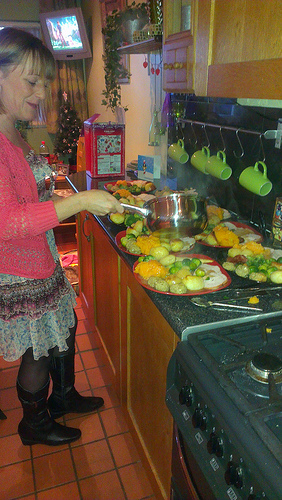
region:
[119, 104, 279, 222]
coffee cups hanging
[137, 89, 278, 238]
green coffee cups hanging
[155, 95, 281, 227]
coffee cups hanging on hooks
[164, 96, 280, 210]
green coffee cups hanging on hooks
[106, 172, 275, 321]
plates of food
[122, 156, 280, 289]
plates of food on the counter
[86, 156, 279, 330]
food on plates on the counter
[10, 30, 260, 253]
a woman holding a pot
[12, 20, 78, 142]
a woman that is smiling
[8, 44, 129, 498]
a woman wearing boots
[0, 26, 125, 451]
Woman preparing a meal in the kitchen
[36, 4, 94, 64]
TV monitor hanging on the wall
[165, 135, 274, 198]
Four green hanging cups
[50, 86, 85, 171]
Small Christmas tree in the corner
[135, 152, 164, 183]
Christmas card on the counter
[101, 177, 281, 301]
Plates full of food on the counter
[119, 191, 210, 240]
Stainless steel pot the woman is holding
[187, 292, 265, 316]
Dirty spoon lying on the counter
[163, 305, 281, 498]
Black range next to the counter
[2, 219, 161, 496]
Brown floor tile in the kitchen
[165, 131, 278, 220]
green mugs hanging on rack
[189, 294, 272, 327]
silver spoon on table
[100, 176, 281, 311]
plates of food on counter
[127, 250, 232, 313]
red plate on counter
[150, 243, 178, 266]
potatoes on plate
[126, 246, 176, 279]
butternut on plate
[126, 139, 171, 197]
christmas card on counter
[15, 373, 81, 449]
lady wearing boots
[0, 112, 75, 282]
lady wearing pink cardigan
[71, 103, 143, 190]
box on the counter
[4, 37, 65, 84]
woman has blonde hair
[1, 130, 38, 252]
woman has pink blouse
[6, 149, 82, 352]
green and blue dress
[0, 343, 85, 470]
woman has black boots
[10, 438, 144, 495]
orange and tiled floor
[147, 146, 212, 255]
woman holds steel pot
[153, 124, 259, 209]
green mugs on wall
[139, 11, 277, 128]
brown cabinets above stove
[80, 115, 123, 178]
red box on counter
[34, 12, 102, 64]
television attached to wall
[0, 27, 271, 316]
the woman is serving a meal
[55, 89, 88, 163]
a Christmas tree is in the background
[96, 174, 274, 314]
the plates are full of food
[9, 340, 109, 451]
the woman is wearing black boots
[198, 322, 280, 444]
a portion of the stove top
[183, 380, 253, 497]
knobs for the stove and the oven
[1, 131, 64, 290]
the woman is wearing a pink knit sweater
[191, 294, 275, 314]
a spoon rests on the counter top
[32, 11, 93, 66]
the television is on in the background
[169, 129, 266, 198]
cups hang above the counter top